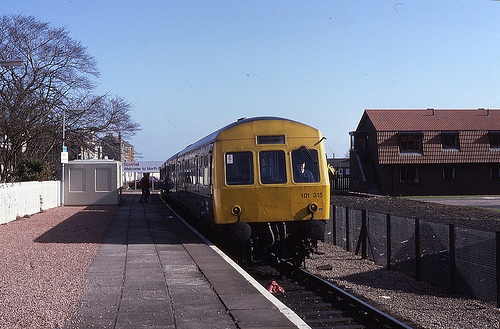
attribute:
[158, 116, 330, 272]
train — yellow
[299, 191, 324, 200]
number — 101 315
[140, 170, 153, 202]
people — standing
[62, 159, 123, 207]
building — white, brown, small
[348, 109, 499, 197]
building — brown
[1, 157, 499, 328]
train station — brown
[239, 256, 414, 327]
track — black, metal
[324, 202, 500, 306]
fence — small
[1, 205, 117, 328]
rocks — brown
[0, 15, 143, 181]
trees — leaf-less, bare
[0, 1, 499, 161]
sky — clear, blue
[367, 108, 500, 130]
roof — brown, red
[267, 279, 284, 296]
object — red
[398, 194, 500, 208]
concrete — gray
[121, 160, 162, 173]
banner — white